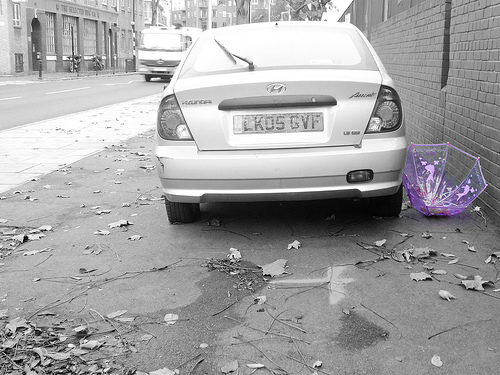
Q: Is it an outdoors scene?
A: Yes, it is outdoors.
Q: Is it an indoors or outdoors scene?
A: It is outdoors.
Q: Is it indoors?
A: No, it is outdoors.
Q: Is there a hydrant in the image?
A: No, there are no fire hydrants.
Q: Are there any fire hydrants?
A: No, there are no fire hydrants.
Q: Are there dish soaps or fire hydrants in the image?
A: No, there are no fire hydrants or dish soaps.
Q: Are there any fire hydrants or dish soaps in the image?
A: No, there are no fire hydrants or dish soaps.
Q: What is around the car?
A: The leaves are around the car.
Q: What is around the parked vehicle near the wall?
A: The leaves are around the car.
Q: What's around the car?
A: The leaves are around the car.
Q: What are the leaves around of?
A: The leaves are around the car.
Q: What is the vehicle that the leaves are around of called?
A: The vehicle is a car.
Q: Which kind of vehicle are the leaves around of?
A: The leaves are around the car.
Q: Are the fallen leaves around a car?
A: Yes, the leaves are around a car.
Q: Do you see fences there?
A: No, there are no fences.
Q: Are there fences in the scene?
A: No, there are no fences.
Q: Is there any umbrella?
A: Yes, there is an umbrella.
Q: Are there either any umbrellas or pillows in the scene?
A: Yes, there is an umbrella.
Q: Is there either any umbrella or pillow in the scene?
A: Yes, there is an umbrella.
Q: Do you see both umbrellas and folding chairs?
A: No, there is an umbrella but no folding chairs.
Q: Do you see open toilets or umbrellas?
A: Yes, there is an open umbrella.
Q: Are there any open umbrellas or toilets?
A: Yes, there is an open umbrella.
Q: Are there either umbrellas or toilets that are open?
A: Yes, the umbrella is open.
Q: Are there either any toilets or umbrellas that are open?
A: Yes, the umbrella is open.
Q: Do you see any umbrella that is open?
A: Yes, there is an open umbrella.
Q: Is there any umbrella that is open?
A: Yes, there is an umbrella that is open.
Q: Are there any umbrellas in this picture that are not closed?
A: Yes, there is a open umbrella.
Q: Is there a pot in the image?
A: No, there are no pots.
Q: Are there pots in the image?
A: No, there are no pots.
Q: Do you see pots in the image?
A: No, there are no pots.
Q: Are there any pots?
A: No, there are no pots.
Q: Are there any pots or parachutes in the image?
A: No, there are no pots or parachutes.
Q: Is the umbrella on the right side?
A: Yes, the umbrella is on the right of the image.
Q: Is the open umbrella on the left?
A: No, the umbrella is on the right of the image.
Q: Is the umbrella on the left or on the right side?
A: The umbrella is on the right of the image.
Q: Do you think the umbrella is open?
A: Yes, the umbrella is open.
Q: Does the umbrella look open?
A: Yes, the umbrella is open.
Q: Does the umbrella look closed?
A: No, the umbrella is open.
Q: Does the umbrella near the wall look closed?
A: No, the umbrella is open.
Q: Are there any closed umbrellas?
A: No, there is an umbrella but it is open.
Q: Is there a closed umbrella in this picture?
A: No, there is an umbrella but it is open.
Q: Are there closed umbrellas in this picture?
A: No, there is an umbrella but it is open.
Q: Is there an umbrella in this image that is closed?
A: No, there is an umbrella but it is open.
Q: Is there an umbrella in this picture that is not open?
A: No, there is an umbrella but it is open.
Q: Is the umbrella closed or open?
A: The umbrella is open.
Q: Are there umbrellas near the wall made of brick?
A: Yes, there is an umbrella near the wall.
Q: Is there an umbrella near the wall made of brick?
A: Yes, there is an umbrella near the wall.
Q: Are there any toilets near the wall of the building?
A: No, there is an umbrella near the wall.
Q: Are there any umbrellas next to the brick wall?
A: Yes, there is an umbrella next to the wall.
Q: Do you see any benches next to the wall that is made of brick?
A: No, there is an umbrella next to the wall.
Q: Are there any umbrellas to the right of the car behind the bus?
A: Yes, there is an umbrella to the right of the car.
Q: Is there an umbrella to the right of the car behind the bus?
A: Yes, there is an umbrella to the right of the car.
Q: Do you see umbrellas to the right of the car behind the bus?
A: Yes, there is an umbrella to the right of the car.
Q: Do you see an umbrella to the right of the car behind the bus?
A: Yes, there is an umbrella to the right of the car.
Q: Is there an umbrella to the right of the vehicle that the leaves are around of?
A: Yes, there is an umbrella to the right of the car.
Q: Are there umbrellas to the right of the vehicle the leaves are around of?
A: Yes, there is an umbrella to the right of the car.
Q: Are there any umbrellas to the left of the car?
A: No, the umbrella is to the right of the car.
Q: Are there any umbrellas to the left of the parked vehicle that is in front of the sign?
A: No, the umbrella is to the right of the car.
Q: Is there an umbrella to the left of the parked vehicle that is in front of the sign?
A: No, the umbrella is to the right of the car.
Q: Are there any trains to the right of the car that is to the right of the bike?
A: No, there is an umbrella to the right of the car.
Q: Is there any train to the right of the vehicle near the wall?
A: No, there is an umbrella to the right of the car.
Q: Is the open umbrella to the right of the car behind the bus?
A: Yes, the umbrella is to the right of the car.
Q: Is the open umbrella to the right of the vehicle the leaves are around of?
A: Yes, the umbrella is to the right of the car.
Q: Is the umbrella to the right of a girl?
A: No, the umbrella is to the right of the car.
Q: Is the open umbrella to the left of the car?
A: No, the umbrella is to the right of the car.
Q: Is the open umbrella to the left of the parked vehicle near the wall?
A: No, the umbrella is to the right of the car.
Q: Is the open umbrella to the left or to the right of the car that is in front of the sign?
A: The umbrella is to the right of the car.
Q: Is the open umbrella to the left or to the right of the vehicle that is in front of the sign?
A: The umbrella is to the right of the car.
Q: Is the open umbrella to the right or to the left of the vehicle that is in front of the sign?
A: The umbrella is to the right of the car.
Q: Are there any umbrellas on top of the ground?
A: Yes, there is an umbrella on top of the ground.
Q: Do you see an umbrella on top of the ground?
A: Yes, there is an umbrella on top of the ground.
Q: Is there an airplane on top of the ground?
A: No, there is an umbrella on top of the ground.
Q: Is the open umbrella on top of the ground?
A: Yes, the umbrella is on top of the ground.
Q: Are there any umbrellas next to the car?
A: Yes, there is an umbrella next to the car.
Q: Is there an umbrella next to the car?
A: Yes, there is an umbrella next to the car.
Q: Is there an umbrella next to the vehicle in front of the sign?
A: Yes, there is an umbrella next to the car.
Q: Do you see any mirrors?
A: No, there are no mirrors.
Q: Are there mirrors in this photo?
A: No, there are no mirrors.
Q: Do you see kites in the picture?
A: No, there are no kites.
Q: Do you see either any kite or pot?
A: No, there are no kites or pots.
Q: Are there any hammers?
A: No, there are no hammers.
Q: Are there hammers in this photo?
A: No, there are no hammers.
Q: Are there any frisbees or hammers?
A: No, there are no hammers or frisbees.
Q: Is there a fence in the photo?
A: No, there are no fences.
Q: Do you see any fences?
A: No, there are no fences.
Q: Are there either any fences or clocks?
A: No, there are no fences or clocks.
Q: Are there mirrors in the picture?
A: No, there are no mirrors.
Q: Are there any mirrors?
A: No, there are no mirrors.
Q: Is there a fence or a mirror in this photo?
A: No, there are no mirrors or fences.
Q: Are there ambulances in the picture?
A: No, there are no ambulances.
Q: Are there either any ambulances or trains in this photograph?
A: No, there are no ambulances or trains.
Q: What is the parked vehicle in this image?
A: The vehicle is a car.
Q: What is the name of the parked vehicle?
A: The vehicle is a car.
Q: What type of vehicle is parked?
A: The vehicle is a car.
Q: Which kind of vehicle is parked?
A: The vehicle is a car.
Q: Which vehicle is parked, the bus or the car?
A: The car is parked.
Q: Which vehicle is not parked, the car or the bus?
A: The bus is not parked.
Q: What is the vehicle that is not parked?
A: The vehicle is a bus.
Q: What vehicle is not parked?
A: The vehicle is a bus.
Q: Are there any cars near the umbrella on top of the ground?
A: Yes, there is a car near the umbrella.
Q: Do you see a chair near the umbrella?
A: No, there is a car near the umbrella.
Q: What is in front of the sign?
A: The car is in front of the sign.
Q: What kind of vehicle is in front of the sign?
A: The vehicle is a car.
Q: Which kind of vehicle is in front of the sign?
A: The vehicle is a car.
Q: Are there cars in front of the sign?
A: Yes, there is a car in front of the sign.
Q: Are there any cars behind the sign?
A: No, the car is in front of the sign.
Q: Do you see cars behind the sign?
A: No, the car is in front of the sign.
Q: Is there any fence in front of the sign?
A: No, there is a car in front of the sign.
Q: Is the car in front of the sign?
A: Yes, the car is in front of the sign.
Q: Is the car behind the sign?
A: No, the car is in front of the sign.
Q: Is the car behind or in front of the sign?
A: The car is in front of the sign.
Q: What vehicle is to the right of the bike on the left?
A: The vehicle is a car.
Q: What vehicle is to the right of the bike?
A: The vehicle is a car.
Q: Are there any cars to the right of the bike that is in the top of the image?
A: Yes, there is a car to the right of the bike.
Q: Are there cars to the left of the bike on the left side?
A: No, the car is to the right of the bike.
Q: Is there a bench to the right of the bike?
A: No, there is a car to the right of the bike.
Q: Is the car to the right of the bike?
A: Yes, the car is to the right of the bike.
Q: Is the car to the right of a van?
A: No, the car is to the right of the bike.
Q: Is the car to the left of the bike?
A: No, the car is to the right of the bike.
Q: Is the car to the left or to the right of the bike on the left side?
A: The car is to the right of the bike.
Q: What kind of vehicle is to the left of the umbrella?
A: The vehicle is a car.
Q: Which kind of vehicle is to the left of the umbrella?
A: The vehicle is a car.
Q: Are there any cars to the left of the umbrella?
A: Yes, there is a car to the left of the umbrella.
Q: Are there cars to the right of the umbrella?
A: No, the car is to the left of the umbrella.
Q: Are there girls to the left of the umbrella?
A: No, there is a car to the left of the umbrella.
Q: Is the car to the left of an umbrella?
A: Yes, the car is to the left of an umbrella.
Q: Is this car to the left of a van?
A: No, the car is to the left of an umbrella.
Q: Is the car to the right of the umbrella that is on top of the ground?
A: No, the car is to the left of the umbrella.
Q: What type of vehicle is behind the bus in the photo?
A: The vehicle is a car.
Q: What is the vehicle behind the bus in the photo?
A: The vehicle is a car.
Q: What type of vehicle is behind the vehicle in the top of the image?
A: The vehicle is a car.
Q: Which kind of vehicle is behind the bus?
A: The vehicle is a car.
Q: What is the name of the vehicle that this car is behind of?
A: The vehicle is a bus.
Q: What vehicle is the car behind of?
A: The car is behind the bus.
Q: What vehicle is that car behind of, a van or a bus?
A: The car is behind a bus.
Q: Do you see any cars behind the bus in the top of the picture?
A: Yes, there is a car behind the bus.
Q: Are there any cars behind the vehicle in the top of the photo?
A: Yes, there is a car behind the bus.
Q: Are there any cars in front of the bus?
A: No, the car is behind the bus.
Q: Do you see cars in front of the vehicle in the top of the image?
A: No, the car is behind the bus.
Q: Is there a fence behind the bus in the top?
A: No, there is a car behind the bus.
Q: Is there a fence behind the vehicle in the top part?
A: No, there is a car behind the bus.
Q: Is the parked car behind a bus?
A: Yes, the car is behind a bus.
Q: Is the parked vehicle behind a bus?
A: Yes, the car is behind a bus.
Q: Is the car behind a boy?
A: No, the car is behind a bus.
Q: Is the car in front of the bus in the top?
A: No, the car is behind the bus.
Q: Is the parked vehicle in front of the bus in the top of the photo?
A: No, the car is behind the bus.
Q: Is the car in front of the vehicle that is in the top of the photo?
A: No, the car is behind the bus.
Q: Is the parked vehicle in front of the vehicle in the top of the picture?
A: No, the car is behind the bus.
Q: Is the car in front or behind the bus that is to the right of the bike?
A: The car is behind the bus.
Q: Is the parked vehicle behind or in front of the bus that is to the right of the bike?
A: The car is behind the bus.